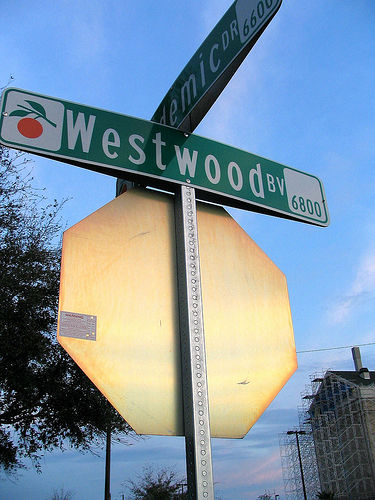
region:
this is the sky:
[21, 10, 151, 79]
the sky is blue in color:
[5, 3, 115, 61]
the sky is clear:
[9, 8, 131, 58]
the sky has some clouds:
[340, 272, 374, 319]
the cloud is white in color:
[352, 267, 369, 299]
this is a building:
[300, 351, 373, 498]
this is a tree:
[4, 219, 62, 431]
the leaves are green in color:
[8, 269, 47, 360]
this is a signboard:
[85, 232, 164, 360]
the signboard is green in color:
[106, 115, 132, 130]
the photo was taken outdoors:
[0, 4, 372, 495]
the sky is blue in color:
[1, 0, 373, 496]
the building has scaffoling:
[281, 369, 373, 495]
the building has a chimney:
[348, 344, 367, 374]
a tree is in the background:
[122, 469, 203, 497]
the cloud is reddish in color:
[213, 442, 311, 490]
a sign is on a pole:
[0, 79, 330, 233]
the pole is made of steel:
[172, 179, 220, 497]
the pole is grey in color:
[173, 182, 222, 498]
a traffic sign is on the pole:
[57, 180, 296, 440]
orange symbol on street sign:
[6, 90, 62, 157]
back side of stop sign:
[58, 195, 298, 435]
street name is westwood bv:
[1, 87, 331, 229]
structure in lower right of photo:
[285, 348, 371, 490]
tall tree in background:
[3, 156, 140, 468]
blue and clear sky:
[2, 2, 372, 365]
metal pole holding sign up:
[181, 187, 202, 492]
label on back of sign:
[57, 311, 97, 344]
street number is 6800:
[285, 171, 330, 232]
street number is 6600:
[242, 0, 282, 40]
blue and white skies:
[248, 81, 313, 138]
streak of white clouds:
[234, 460, 282, 485]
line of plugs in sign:
[178, 306, 207, 386]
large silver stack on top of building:
[338, 337, 372, 381]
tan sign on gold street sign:
[43, 300, 111, 343]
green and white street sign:
[210, 149, 313, 214]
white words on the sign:
[180, 150, 270, 194]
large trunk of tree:
[88, 437, 131, 486]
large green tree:
[14, 284, 54, 376]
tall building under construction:
[314, 361, 364, 462]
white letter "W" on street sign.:
[61, 105, 96, 157]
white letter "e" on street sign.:
[97, 115, 118, 160]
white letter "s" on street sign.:
[120, 120, 146, 167]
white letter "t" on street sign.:
[146, 129, 168, 166]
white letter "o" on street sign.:
[201, 150, 221, 183]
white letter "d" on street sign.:
[244, 152, 259, 192]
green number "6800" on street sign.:
[285, 188, 319, 212]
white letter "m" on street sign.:
[173, 71, 195, 105]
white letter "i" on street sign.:
[191, 47, 208, 85]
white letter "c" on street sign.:
[203, 37, 221, 70]